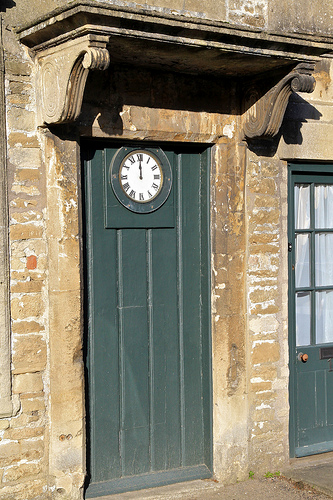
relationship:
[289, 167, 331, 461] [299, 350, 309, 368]
door has handle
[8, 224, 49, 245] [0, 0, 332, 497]
brick in building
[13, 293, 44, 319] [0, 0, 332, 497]
brick in building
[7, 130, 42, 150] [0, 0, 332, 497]
brick in building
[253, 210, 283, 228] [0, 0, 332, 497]
brick in building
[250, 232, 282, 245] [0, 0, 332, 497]
brick in building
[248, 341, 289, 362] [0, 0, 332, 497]
brick in building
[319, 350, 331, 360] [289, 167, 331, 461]
slot in door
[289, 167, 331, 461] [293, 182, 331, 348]
door has window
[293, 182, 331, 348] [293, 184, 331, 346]
window has curtain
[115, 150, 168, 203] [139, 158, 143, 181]
clock has hand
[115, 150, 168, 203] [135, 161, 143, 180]
clock has hand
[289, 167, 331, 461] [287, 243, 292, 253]
door has doorbell